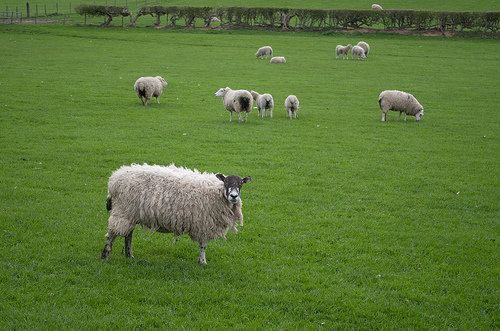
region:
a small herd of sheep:
[85, 15, 481, 314]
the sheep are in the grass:
[76, 26, 460, 298]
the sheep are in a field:
[72, 12, 474, 318]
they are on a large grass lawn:
[88, 31, 477, 308]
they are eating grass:
[244, 15, 313, 77]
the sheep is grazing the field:
[343, 70, 439, 135]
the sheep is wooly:
[68, 118, 268, 304]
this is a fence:
[2, 0, 87, 42]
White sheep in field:
[378, 88, 428, 125]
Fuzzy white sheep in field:
[103, 158, 248, 270]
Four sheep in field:
[131, 74, 303, 119]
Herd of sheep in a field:
[97, 38, 428, 263]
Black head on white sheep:
[212, 171, 252, 201]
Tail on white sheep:
[105, 190, 115, 210]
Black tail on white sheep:
[239, 97, 250, 109]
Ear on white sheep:
[216, 173, 227, 181]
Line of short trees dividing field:
[77, 1, 497, 32]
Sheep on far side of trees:
[369, 2, 385, 9]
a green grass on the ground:
[332, 180, 418, 230]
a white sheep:
[111, 155, 182, 225]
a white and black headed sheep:
[210, 165, 255, 225]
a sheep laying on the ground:
[267, 53, 297, 68]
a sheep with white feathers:
[99, 143, 261, 247]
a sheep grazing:
[372, 80, 434, 148]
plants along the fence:
[66, 5, 175, 23]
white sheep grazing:
[336, 35, 378, 68]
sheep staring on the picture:
[88, 150, 278, 262]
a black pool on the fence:
[24, 5, 35, 18]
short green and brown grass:
[300, 156, 340, 198]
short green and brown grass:
[398, 211, 442, 251]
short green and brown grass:
[290, 141, 364, 222]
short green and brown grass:
[285, 249, 343, 290]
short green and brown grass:
[20, 250, 50, 280]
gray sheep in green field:
[82, 145, 247, 277]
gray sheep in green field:
[126, 55, 177, 122]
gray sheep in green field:
[271, 75, 307, 135]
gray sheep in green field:
[360, 82, 443, 152]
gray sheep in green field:
[201, 72, 292, 130]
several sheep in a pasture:
[46, 36, 459, 266]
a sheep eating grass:
[363, 75, 442, 145]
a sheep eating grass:
[281, 85, 324, 137]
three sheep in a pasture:
[324, 29, 404, 81]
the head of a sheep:
[212, 165, 255, 206]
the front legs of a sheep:
[193, 235, 214, 270]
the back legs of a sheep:
[88, 217, 142, 267]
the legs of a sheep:
[98, 224, 218, 273]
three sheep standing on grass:
[211, 75, 307, 138]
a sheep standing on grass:
[73, 133, 336, 310]